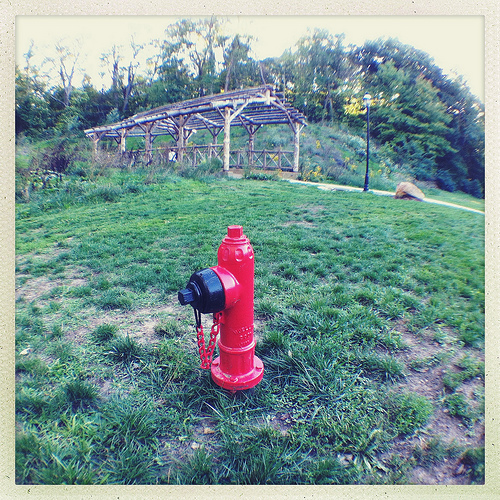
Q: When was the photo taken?
A: During daylight hours.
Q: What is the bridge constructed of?
A: Logs.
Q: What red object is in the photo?
A: Fire hydrant.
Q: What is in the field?
A: A fire hydrant.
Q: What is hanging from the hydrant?
A: A chain.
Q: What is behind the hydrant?
A: A structure.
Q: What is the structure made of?
A: Wood.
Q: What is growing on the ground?
A: Grass.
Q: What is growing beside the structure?
A: Trees.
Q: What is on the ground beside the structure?
A: A path.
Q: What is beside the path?
A: A pole.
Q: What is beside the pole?
A: A stone.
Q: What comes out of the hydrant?
A: Water.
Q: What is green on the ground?
A: Grass.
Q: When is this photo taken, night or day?
A: Daytime.